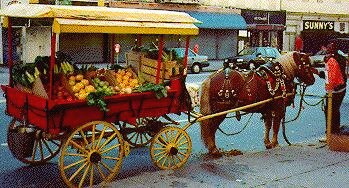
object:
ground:
[239, 136, 259, 148]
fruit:
[118, 69, 129, 75]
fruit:
[94, 87, 106, 92]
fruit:
[79, 77, 89, 85]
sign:
[305, 20, 335, 31]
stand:
[2, 41, 197, 142]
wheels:
[146, 124, 196, 171]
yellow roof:
[3, 2, 200, 36]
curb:
[298, 82, 310, 93]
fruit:
[123, 78, 135, 85]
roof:
[3, 3, 210, 24]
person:
[318, 41, 345, 142]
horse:
[200, 50, 317, 158]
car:
[168, 45, 210, 73]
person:
[319, 46, 348, 144]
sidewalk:
[265, 164, 348, 187]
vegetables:
[18, 63, 31, 80]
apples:
[97, 79, 108, 86]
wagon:
[3, 3, 208, 181]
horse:
[192, 50, 310, 158]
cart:
[3, 4, 201, 187]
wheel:
[150, 122, 195, 171]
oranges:
[116, 74, 126, 83]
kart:
[1, 4, 205, 186]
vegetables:
[57, 59, 73, 74]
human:
[315, 39, 345, 144]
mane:
[279, 55, 294, 78]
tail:
[197, 76, 213, 148]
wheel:
[56, 118, 126, 188]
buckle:
[266, 58, 288, 82]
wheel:
[64, 123, 124, 187]